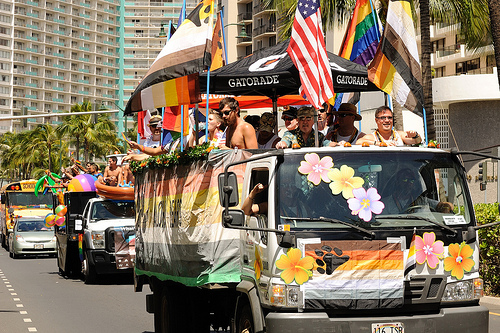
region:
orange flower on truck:
[275, 248, 315, 284]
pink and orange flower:
[411, 233, 476, 283]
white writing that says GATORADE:
[223, 73, 285, 89]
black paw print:
[313, 246, 353, 276]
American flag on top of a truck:
[289, 1, 336, 106]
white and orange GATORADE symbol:
[250, 51, 286, 71]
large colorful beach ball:
[66, 172, 101, 194]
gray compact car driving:
[7, 215, 57, 256]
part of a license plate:
[367, 318, 410, 332]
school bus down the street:
[0, 176, 65, 233]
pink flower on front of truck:
[293, 149, 344, 178]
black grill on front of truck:
[400, 270, 465, 303]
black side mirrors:
[210, 143, 307, 250]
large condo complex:
[13, 22, 138, 104]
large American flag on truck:
[289, 5, 342, 175]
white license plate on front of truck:
[356, 315, 409, 331]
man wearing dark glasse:
[208, 96, 253, 121]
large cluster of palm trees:
[17, 95, 169, 173]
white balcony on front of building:
[427, 44, 497, 140]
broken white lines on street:
[3, 288, 45, 321]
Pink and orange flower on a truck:
[406, 218, 486, 276]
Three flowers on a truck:
[274, 148, 390, 227]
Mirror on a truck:
[206, 160, 297, 244]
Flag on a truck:
[128, 6, 291, 111]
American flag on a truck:
[288, 6, 362, 122]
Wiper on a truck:
[275, 203, 397, 255]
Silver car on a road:
[11, 211, 70, 261]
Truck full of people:
[36, 157, 158, 275]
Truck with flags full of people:
[120, 84, 499, 269]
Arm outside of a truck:
[224, 158, 299, 233]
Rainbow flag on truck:
[333, 6, 396, 158]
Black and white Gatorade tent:
[205, 45, 295, 87]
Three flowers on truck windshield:
[295, 155, 396, 222]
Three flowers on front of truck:
[273, 235, 481, 321]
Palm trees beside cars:
[11, 107, 109, 204]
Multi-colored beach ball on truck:
[51, 160, 105, 228]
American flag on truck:
[286, 6, 340, 158]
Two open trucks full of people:
[52, 82, 260, 244]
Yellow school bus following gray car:
[5, 169, 62, 257]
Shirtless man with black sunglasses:
[213, 91, 263, 153]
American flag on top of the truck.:
[288, 0, 340, 110]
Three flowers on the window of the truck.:
[293, 150, 385, 225]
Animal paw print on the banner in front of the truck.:
[307, 246, 357, 277]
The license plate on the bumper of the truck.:
[368, 321, 408, 331]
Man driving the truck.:
[386, 166, 446, 217]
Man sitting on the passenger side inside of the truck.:
[248, 171, 316, 218]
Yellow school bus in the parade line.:
[1, 176, 61, 228]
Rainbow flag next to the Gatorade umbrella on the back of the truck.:
[341, 2, 383, 64]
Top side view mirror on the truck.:
[217, 163, 237, 207]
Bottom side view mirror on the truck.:
[218, 209, 243, 226]